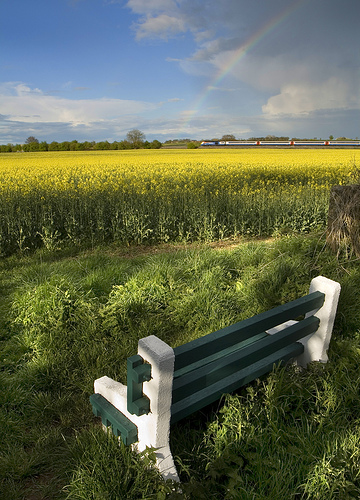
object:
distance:
[0, 81, 359, 150]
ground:
[188, 146, 360, 180]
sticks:
[169, 290, 326, 426]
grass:
[1, 260, 358, 298]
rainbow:
[183, 2, 297, 132]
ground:
[301, 125, 315, 142]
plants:
[2, 148, 352, 248]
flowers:
[0, 147, 359, 255]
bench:
[89, 274, 341, 497]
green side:
[127, 355, 151, 417]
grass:
[102, 401, 335, 488]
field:
[2, 141, 352, 448]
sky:
[0, 0, 347, 142]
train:
[197, 138, 360, 149]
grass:
[1, 194, 346, 233]